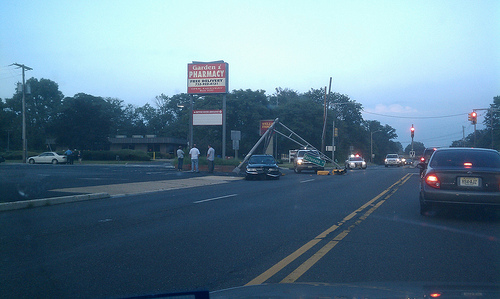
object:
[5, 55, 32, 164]
telephone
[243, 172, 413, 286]
lines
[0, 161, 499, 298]
highway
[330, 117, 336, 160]
post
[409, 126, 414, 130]
lights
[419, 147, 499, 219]
car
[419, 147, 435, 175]
car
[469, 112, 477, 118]
lights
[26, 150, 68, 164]
car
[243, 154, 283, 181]
car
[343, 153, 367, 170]
car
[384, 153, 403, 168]
car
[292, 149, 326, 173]
car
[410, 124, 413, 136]
stop light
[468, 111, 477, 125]
stop light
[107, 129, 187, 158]
building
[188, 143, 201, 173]
men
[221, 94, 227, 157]
pole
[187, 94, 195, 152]
pole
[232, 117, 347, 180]
accident scene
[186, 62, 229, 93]
red sign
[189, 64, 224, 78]
white text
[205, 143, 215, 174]
men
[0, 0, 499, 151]
sky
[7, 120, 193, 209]
parking lot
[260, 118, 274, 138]
sign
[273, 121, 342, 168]
pole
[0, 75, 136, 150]
trees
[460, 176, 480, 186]
license plate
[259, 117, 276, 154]
street sign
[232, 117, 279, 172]
pole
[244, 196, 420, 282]
surface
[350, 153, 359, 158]
lights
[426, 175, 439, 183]
lights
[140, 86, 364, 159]
trees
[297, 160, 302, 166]
light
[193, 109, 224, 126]
sign